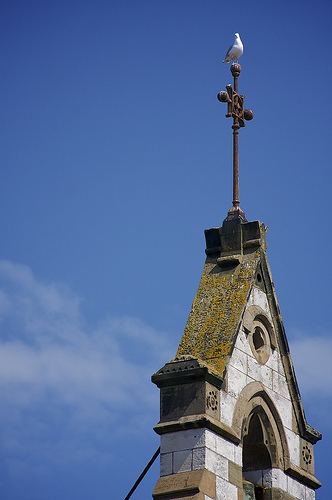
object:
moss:
[173, 253, 257, 374]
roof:
[151, 221, 327, 442]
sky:
[0, 0, 330, 500]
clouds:
[1, 337, 103, 410]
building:
[151, 62, 323, 500]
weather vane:
[217, 62, 252, 218]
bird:
[223, 32, 244, 63]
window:
[251, 329, 263, 350]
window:
[242, 411, 272, 499]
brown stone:
[152, 467, 216, 500]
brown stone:
[228, 461, 243, 490]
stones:
[246, 355, 274, 390]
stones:
[157, 428, 214, 454]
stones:
[205, 448, 229, 481]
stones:
[272, 368, 293, 402]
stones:
[262, 468, 288, 491]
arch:
[233, 380, 291, 498]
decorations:
[207, 391, 219, 413]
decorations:
[301, 446, 311, 467]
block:
[158, 379, 220, 420]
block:
[300, 438, 316, 476]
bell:
[243, 480, 256, 500]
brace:
[125, 445, 160, 500]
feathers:
[228, 43, 235, 58]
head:
[233, 32, 240, 40]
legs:
[232, 59, 234, 65]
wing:
[226, 45, 234, 57]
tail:
[222, 59, 229, 64]